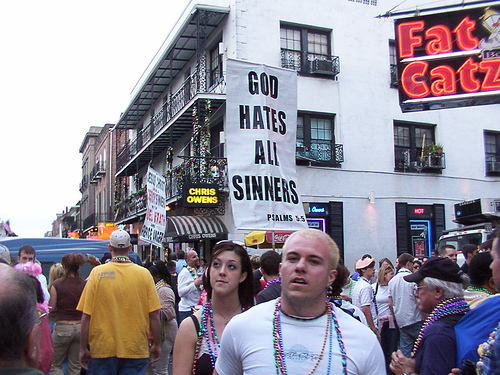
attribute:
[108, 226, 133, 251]
cap — white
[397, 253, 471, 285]
cap — black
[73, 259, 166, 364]
shirt — yellow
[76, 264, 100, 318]
sleeve — short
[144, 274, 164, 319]
sleeve — short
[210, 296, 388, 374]
shirt — white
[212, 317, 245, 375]
sleeve — short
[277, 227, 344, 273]
hair — short, blonde, neat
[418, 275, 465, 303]
hair — white